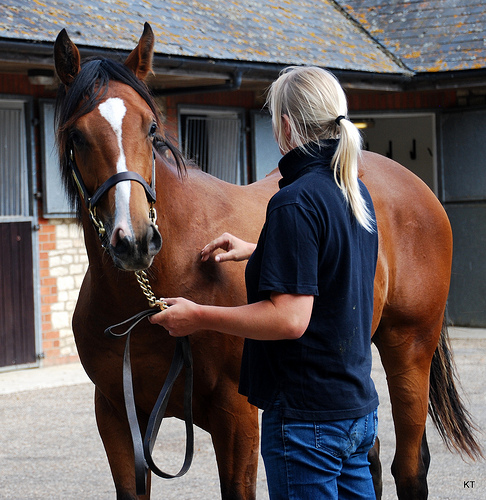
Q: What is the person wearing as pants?
A: Blue jeans.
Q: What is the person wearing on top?
A: Dark blue shirt with collar.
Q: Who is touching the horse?
A: Lady wearing blue shirt.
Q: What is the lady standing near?
A: Horse.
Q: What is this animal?
A: A Horse.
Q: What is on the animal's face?
A: Leather bridle.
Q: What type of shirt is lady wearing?
A: Black polo.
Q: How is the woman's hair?
A: Ponytail.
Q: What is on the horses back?
A: Fur.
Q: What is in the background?
A: Wooden stable.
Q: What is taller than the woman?
A: Horse.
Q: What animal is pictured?
A: A horse.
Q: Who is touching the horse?
A: A woman.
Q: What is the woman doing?
A: Stroking the horse.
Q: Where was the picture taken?
A: Outside of a building.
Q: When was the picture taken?
A: During day hours.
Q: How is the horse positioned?
A: Standing.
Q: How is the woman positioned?
A: Standing.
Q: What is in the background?
A: A building.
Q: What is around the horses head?
A: Reins.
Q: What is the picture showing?
A: A woman and a horse.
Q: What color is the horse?
A: Brown.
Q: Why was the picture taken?
A: To capture the women and horse.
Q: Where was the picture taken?
A: A horse stable.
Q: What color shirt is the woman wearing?
A: Blue.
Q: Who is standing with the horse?
A: A woman.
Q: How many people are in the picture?
A: One.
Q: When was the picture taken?
A: During the day.